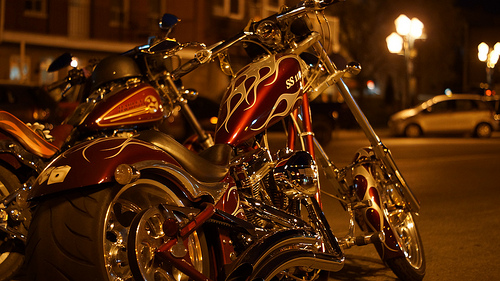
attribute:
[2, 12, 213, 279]
motorcycle — red 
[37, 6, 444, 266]
motorcycle — red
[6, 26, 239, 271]
motorcycle — red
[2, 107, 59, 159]
section — orange 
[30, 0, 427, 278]
motorcycle — parked, shiny, lit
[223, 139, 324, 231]
engine — chrome 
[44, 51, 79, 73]
mirror — rear view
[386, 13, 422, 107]
streetlight — lit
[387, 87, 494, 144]
van — blurry, mini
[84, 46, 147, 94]
helmet — black, motorcycle, bucket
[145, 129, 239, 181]
seat — black 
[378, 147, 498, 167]
line — white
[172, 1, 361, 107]
handlebars — metal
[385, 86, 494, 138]
van — gray 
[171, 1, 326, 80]
handlebar — silver 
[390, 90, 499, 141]
car — silver color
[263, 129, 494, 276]
asphalt — grey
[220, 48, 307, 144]
flame — custom, gray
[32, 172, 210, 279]
fat/back tire — black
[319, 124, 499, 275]
street — asphalt